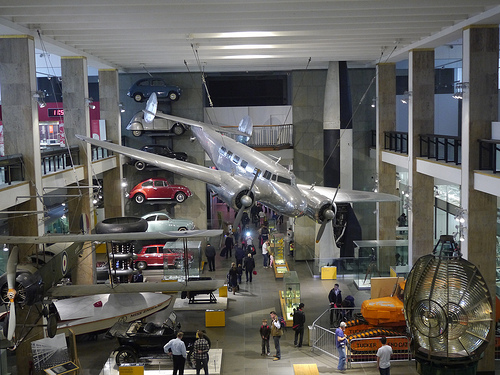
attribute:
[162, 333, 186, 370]
man — talking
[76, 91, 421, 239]
airplane — silver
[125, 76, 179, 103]
vw bug — red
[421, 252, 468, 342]
fan — black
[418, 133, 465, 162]
railing — black, metal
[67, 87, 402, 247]
plane — gray, silver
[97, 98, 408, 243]
plane — silver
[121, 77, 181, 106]
car — blue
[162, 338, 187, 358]
shirt — white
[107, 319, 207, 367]
car — old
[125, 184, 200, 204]
car — red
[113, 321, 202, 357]
car — old